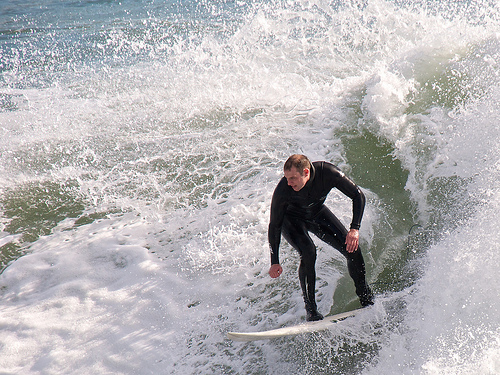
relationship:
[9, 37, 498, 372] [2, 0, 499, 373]
wave in ocean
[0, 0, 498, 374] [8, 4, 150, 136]
wave in ocean